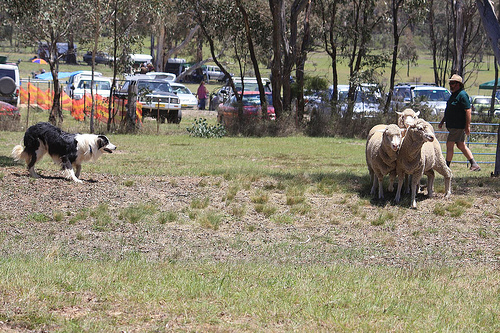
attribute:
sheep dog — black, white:
[8, 118, 116, 185]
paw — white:
[65, 171, 83, 185]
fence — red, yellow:
[61, 100, 196, 114]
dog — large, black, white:
[8, 118, 122, 196]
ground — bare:
[1, 128, 497, 331]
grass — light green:
[0, 105, 500, 330]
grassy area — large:
[0, 132, 499, 331]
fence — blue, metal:
[423, 120, 497, 163]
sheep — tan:
[356, 98, 456, 213]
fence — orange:
[13, 78, 140, 130]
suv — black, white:
[3, 64, 23, 106]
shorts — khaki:
[447, 125, 466, 142]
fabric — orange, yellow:
[22, 81, 145, 128]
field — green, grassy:
[1, 50, 496, 330]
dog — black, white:
[28, 124, 115, 205]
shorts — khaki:
[440, 119, 476, 149]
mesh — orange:
[12, 86, 140, 126]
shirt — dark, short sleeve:
[432, 63, 480, 137]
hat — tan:
[418, 50, 480, 190]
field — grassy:
[205, 197, 291, 255]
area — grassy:
[150, 138, 293, 226]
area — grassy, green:
[182, 192, 332, 263]